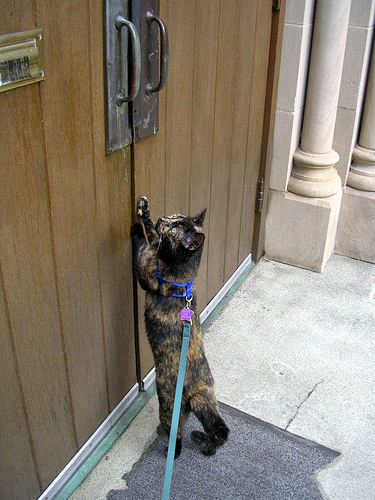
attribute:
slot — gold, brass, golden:
[1, 23, 46, 93]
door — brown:
[1, 1, 288, 499]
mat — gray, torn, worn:
[104, 402, 342, 500]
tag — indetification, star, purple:
[178, 306, 194, 323]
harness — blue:
[154, 273, 192, 298]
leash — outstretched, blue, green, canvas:
[158, 320, 192, 500]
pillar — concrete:
[285, 1, 353, 198]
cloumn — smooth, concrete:
[345, 27, 374, 192]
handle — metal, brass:
[117, 17, 142, 107]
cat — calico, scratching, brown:
[130, 196, 230, 458]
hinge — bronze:
[254, 178, 266, 216]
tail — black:
[189, 392, 230, 457]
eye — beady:
[170, 225, 180, 235]